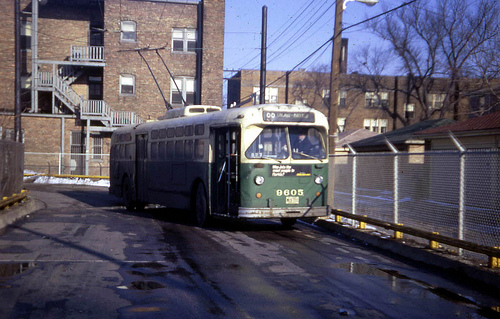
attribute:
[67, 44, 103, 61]
railing — metal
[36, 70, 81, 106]
railing — metal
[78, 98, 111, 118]
railing — metal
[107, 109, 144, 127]
railing — metal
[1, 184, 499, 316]
street — wet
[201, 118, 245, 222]
door —  bus' , the front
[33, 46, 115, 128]
stairs — gray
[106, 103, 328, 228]
bus — green and white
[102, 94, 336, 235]
bus — green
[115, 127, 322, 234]
bus — green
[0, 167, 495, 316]
street — black, wet, paved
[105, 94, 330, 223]
bus — green and white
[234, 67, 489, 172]
apartment building — brick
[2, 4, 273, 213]
building — brown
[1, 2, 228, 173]
apartment building — brick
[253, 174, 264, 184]
headlight —  off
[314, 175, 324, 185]
headlight —  off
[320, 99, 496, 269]
fence — metal, cyclone style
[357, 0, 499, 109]
trees — bare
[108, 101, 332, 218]
bus — green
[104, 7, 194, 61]
building — brown, brick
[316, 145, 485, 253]
fence — chain linked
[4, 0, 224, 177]
building — large, brick